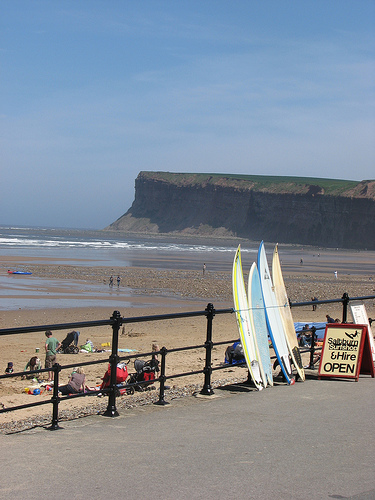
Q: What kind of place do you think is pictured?
A: It is a beach.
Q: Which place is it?
A: It is a beach.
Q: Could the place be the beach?
A: Yes, it is the beach.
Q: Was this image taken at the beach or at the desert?
A: It was taken at the beach.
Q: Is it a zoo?
A: No, it is a beach.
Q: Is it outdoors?
A: Yes, it is outdoors.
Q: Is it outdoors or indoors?
A: It is outdoors.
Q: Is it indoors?
A: No, it is outdoors.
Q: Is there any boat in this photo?
A: Yes, there is a boat.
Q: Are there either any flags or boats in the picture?
A: Yes, there is a boat.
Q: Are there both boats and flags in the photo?
A: No, there is a boat but no flags.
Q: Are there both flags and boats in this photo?
A: No, there is a boat but no flags.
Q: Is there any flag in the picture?
A: No, there are no flags.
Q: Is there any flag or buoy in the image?
A: No, there are no flags or buoys.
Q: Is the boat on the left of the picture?
A: Yes, the boat is on the left of the image.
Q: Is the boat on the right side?
A: No, the boat is on the left of the image.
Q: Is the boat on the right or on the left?
A: The boat is on the left of the image.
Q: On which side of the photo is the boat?
A: The boat is on the left of the image.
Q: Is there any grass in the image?
A: Yes, there is grass.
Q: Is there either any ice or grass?
A: Yes, there is grass.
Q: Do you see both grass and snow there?
A: No, there is grass but no snow.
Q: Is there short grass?
A: Yes, there is short grass.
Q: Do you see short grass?
A: Yes, there is short grass.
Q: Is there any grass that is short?
A: Yes, there is grass that is short.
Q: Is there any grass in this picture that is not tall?
A: Yes, there is short grass.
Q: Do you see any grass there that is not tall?
A: Yes, there is short grass.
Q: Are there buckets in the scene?
A: No, there are no buckets.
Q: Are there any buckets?
A: No, there are no buckets.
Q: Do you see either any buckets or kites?
A: No, there are no buckets or kites.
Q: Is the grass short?
A: Yes, the grass is short.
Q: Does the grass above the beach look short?
A: Yes, the grass is short.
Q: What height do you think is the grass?
A: The grass is short.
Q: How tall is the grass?
A: The grass is short.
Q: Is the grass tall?
A: No, the grass is short.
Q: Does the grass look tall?
A: No, the grass is short.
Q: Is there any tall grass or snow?
A: No, there is grass but it is short.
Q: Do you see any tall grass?
A: No, there is grass but it is short.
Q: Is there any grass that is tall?
A: No, there is grass but it is short.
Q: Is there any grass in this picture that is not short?
A: No, there is grass but it is short.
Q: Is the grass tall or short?
A: The grass is short.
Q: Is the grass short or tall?
A: The grass is short.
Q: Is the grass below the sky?
A: Yes, the grass is below the sky.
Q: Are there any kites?
A: No, there are no kites.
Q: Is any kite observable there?
A: No, there are no kites.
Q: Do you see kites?
A: No, there are no kites.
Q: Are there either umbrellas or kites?
A: No, there are no kites or umbrellas.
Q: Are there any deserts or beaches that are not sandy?
A: No, there is a beach but it is sandy.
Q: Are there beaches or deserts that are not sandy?
A: No, there is a beach but it is sandy.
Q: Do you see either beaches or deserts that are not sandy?
A: No, there is a beach but it is sandy.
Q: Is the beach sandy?
A: Yes, the beach is sandy.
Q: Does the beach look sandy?
A: Yes, the beach is sandy.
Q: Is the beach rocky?
A: No, the beach is sandy.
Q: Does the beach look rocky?
A: No, the beach is sandy.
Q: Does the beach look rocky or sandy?
A: The beach is sandy.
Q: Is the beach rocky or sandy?
A: The beach is sandy.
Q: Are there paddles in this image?
A: No, there are no paddles.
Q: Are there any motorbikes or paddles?
A: No, there are no paddles or motorbikes.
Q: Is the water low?
A: Yes, the water is low.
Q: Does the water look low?
A: Yes, the water is low.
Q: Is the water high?
A: No, the water is low.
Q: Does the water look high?
A: No, the water is low.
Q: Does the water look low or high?
A: The water is low.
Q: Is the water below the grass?
A: Yes, the water is below the grass.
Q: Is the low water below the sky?
A: Yes, the water is below the sky.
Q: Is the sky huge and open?
A: Yes, the sky is huge and open.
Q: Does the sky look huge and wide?
A: Yes, the sky is huge and wide.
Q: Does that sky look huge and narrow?
A: No, the sky is huge but wide.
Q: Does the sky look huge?
A: Yes, the sky is huge.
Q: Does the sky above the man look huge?
A: Yes, the sky is huge.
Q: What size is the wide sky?
A: The sky is huge.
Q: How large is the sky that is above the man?
A: The sky is huge.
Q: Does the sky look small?
A: No, the sky is huge.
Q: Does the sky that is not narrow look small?
A: No, the sky is huge.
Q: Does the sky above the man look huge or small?
A: The sky is huge.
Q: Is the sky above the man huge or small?
A: The sky is huge.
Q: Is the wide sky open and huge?
A: Yes, the sky is open and huge.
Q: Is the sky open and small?
A: No, the sky is open but huge.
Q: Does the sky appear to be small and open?
A: No, the sky is open but huge.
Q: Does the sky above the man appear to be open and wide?
A: Yes, the sky is open and wide.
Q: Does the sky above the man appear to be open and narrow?
A: No, the sky is open but wide.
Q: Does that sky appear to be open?
A: Yes, the sky is open.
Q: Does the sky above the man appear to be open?
A: Yes, the sky is open.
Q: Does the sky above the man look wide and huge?
A: Yes, the sky is wide and huge.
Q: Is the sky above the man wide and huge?
A: Yes, the sky is wide and huge.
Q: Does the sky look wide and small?
A: No, the sky is wide but huge.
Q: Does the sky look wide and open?
A: Yes, the sky is wide and open.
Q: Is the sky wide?
A: Yes, the sky is wide.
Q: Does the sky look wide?
A: Yes, the sky is wide.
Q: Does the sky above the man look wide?
A: Yes, the sky is wide.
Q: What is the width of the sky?
A: The sky is wide.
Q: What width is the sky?
A: The sky is wide.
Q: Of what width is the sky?
A: The sky is wide.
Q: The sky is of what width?
A: The sky is wide.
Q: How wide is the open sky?
A: The sky is wide.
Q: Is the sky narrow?
A: No, the sky is wide.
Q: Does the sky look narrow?
A: No, the sky is wide.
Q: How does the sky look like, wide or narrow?
A: The sky is wide.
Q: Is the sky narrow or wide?
A: The sky is wide.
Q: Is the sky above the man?
A: Yes, the sky is above the man.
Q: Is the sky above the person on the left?
A: Yes, the sky is above the man.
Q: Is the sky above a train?
A: No, the sky is above the man.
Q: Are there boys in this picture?
A: No, there are no boys.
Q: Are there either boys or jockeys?
A: No, there are no boys or jockeys.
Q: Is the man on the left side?
A: Yes, the man is on the left of the image.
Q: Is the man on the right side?
A: No, the man is on the left of the image.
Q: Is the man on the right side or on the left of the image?
A: The man is on the left of the image.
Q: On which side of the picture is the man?
A: The man is on the left of the image.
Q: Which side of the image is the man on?
A: The man is on the left of the image.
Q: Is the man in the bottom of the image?
A: Yes, the man is in the bottom of the image.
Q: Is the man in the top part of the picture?
A: No, the man is in the bottom of the image.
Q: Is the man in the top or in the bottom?
A: The man is in the bottom of the image.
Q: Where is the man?
A: The man is on the beach.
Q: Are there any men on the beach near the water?
A: Yes, there is a man on the beach.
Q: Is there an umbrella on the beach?
A: No, there is a man on the beach.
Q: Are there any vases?
A: No, there are no vases.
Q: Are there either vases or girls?
A: No, there are no vases or girls.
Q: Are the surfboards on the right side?
A: Yes, the surfboards are on the right of the image.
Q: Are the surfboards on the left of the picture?
A: No, the surfboards are on the right of the image.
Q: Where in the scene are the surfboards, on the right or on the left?
A: The surfboards are on the right of the image.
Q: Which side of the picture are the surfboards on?
A: The surfboards are on the right of the image.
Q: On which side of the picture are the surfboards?
A: The surfboards are on the right of the image.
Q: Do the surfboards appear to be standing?
A: Yes, the surfboards are standing.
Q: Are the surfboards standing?
A: Yes, the surfboards are standing.